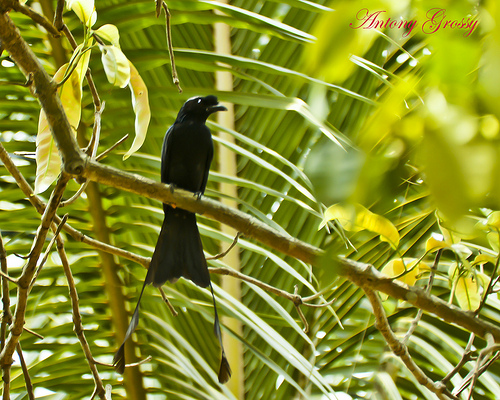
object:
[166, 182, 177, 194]
foot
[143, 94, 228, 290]
bird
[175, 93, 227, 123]
head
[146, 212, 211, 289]
tail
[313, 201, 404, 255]
leaves